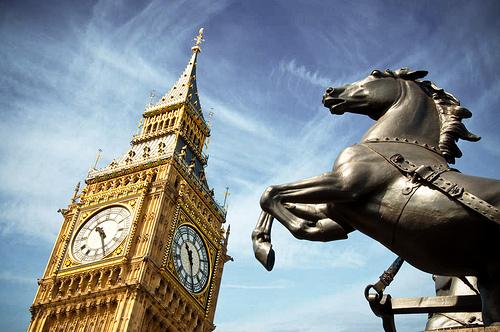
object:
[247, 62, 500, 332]
statue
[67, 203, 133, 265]
clock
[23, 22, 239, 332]
tower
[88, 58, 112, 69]
clouds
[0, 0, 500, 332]
sky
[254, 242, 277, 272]
hooves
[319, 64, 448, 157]
bridle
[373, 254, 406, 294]
rope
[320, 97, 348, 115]
mouth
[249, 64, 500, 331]
horse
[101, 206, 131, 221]
white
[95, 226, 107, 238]
handles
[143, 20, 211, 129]
steeple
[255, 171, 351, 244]
legs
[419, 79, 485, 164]
mane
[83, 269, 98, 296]
arches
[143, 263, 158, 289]
windows